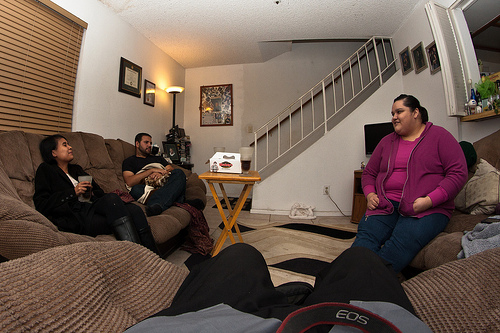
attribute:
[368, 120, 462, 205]
shirt — purple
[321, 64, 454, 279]
woman — sitting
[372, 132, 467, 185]
jacket — purple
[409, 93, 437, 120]
pony tail — purple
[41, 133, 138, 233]
person — sitting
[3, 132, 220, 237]
couch — brown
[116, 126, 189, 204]
person — sitting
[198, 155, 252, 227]
table — wooden, small, wood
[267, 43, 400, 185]
stairs — white, upstairs, here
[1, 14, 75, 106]
curtain — brown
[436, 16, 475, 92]
shutter — white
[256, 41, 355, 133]
railing — metal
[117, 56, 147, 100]
picture — framed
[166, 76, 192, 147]
lamp — standing, here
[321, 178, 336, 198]
outlet — white, electrical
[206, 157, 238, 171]
food — boxed